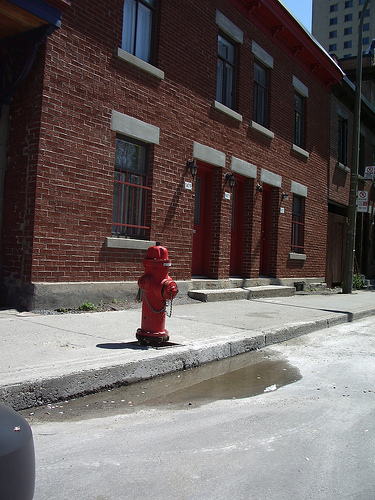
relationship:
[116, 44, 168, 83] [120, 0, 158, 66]
sill on window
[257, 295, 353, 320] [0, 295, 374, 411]
shadow on top of sidewalk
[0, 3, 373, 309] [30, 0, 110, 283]
building has wall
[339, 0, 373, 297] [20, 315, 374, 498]
pole on side of street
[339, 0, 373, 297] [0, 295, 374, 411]
pole on side of sidewalk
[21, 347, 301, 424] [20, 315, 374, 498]
puddle on side of street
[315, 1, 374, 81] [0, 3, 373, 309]
building behind house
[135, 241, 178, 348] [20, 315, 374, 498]
hydrant by street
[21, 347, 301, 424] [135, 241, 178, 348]
puddle by hydrant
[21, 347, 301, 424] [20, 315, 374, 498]
puddle in street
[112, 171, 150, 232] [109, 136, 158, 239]
bars on front of window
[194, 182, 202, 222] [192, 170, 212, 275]
window in door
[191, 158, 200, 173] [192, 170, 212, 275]
light by door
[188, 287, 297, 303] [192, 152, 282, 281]
steps at doorways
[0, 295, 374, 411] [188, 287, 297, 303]
sidewalk along steps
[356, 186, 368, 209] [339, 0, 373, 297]
signs on side of pole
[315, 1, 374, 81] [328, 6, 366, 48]
building has windows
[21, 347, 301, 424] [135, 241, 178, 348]
puddle next to hydrant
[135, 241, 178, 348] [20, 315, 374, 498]
hydrant on street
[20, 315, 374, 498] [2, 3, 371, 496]
street in city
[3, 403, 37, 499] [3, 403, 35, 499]
car has bumper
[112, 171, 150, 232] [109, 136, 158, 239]
bars across window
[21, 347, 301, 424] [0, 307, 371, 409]
puddle beside step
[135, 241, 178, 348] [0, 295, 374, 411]
hydrant on top of sidewalk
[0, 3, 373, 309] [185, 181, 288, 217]
residence has numbers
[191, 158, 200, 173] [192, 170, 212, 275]
light on side of door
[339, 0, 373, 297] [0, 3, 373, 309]
pole in front of building